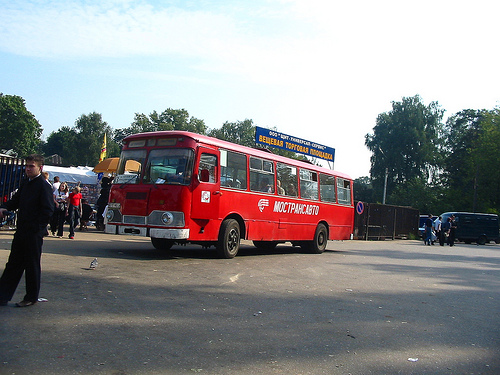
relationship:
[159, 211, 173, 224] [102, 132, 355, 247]
headlight on bus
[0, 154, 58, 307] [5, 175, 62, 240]
man wearing black coat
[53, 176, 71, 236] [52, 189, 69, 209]
person wearing shirt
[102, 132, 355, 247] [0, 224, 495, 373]
bus parked in parking lot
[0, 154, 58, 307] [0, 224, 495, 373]
man in parking lot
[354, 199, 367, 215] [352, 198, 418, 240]
sign on fence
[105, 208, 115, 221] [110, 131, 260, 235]
headlight are on bus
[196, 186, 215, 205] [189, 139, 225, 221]
sign on door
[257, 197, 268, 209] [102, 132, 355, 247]
design on bus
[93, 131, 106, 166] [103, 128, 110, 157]
flag attached to pole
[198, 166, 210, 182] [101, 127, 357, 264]
sideview mirror on bus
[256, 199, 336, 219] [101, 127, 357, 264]
writing on bus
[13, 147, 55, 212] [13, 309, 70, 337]
man on pavement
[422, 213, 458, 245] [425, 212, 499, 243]
people by van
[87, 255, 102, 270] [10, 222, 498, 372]
bird on ground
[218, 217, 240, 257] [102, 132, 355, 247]
tire of bus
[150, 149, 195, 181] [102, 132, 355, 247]
front windshield of bus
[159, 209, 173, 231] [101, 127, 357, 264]
headlight on bus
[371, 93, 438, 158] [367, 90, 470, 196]
tree covered in green leaves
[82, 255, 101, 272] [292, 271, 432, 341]
bird standing on pavement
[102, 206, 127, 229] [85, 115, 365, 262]
headlight on bus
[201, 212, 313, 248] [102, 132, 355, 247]
black tire on bus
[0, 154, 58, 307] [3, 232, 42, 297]
man wearing black pants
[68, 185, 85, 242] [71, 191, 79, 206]
person wearing red shirt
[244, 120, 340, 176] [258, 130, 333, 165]
banner has writing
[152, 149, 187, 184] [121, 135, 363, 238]
window on bus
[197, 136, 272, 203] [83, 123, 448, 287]
window on bus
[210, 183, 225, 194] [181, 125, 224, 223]
handle on door